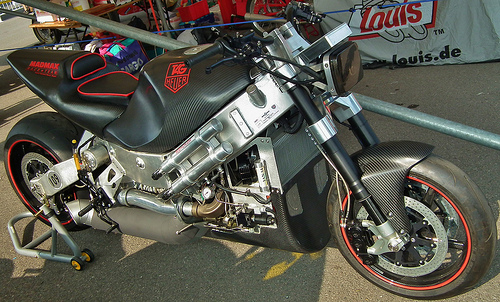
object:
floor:
[154, 262, 317, 302]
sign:
[356, 2, 435, 34]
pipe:
[346, 92, 500, 150]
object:
[390, 45, 463, 67]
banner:
[312, 0, 500, 66]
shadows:
[103, 248, 321, 299]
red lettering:
[26, 61, 63, 77]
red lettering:
[359, 1, 422, 34]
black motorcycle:
[0, 0, 497, 302]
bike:
[1, 1, 497, 299]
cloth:
[306, 0, 499, 71]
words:
[357, 5, 423, 35]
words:
[390, 44, 462, 67]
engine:
[199, 145, 277, 230]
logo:
[344, 1, 437, 38]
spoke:
[285, 77, 397, 240]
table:
[30, 4, 118, 43]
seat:
[67, 52, 139, 96]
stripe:
[338, 176, 472, 290]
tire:
[324, 152, 499, 302]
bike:
[23, 20, 498, 273]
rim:
[338, 176, 468, 291]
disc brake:
[354, 194, 450, 279]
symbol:
[433, 28, 444, 35]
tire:
[4, 111, 88, 233]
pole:
[13, 0, 499, 145]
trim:
[68, 51, 137, 97]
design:
[164, 62, 192, 94]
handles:
[183, 41, 223, 68]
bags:
[97, 38, 149, 75]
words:
[27, 61, 61, 79]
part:
[82, 9, 107, 36]